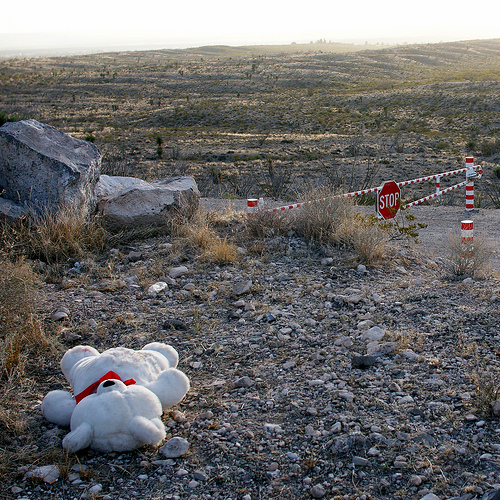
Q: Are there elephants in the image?
A: No, there are no elephants.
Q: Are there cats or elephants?
A: No, there are no elephants or cats.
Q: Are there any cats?
A: No, there are no cats.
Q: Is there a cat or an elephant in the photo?
A: No, there are no cats or elephants.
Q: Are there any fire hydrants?
A: No, there are no fire hydrants.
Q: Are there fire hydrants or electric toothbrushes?
A: No, there are no fire hydrants or electric toothbrushes.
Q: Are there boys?
A: No, there are no boys.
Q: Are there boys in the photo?
A: No, there are no boys.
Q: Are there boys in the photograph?
A: No, there are no boys.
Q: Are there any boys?
A: No, there are no boys.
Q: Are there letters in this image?
A: Yes, there are letters.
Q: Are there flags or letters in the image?
A: Yes, there are letters.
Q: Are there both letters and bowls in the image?
A: No, there are letters but no bowls.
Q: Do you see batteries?
A: No, there are no batteries.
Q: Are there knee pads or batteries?
A: No, there are no batteries or knee pads.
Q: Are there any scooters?
A: No, there are no scooters.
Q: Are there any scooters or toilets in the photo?
A: No, there are no scooters or toilets.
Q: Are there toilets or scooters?
A: No, there are no scooters or toilets.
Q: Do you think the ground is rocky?
A: Yes, the ground is rocky.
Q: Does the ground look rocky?
A: Yes, the ground is rocky.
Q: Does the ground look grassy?
A: No, the ground is rocky.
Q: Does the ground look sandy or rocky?
A: The ground is rocky.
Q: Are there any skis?
A: No, there are no skis.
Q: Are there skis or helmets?
A: No, there are no skis or helmets.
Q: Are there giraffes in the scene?
A: No, there are no giraffes.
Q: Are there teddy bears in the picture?
A: Yes, there is a teddy bear.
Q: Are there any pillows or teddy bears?
A: Yes, there is a teddy bear.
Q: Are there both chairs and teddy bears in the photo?
A: No, there is a teddy bear but no chairs.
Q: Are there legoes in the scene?
A: No, there are no legoes.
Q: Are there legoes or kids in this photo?
A: No, there are no legoes or kids.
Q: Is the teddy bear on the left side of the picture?
A: Yes, the teddy bear is on the left of the image.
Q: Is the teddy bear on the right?
A: No, the teddy bear is on the left of the image.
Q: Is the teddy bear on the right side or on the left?
A: The teddy bear is on the left of the image.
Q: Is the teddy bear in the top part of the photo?
A: No, the teddy bear is in the bottom of the image.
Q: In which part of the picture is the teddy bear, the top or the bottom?
A: The teddy bear is in the bottom of the image.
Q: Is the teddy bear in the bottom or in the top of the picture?
A: The teddy bear is in the bottom of the image.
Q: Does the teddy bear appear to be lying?
A: Yes, the teddy bear is lying.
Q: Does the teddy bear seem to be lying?
A: Yes, the teddy bear is lying.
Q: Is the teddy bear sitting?
A: No, the teddy bear is lying.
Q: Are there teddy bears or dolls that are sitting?
A: No, there is a teddy bear but it is lying.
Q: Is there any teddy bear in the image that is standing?
A: No, there is a teddy bear but it is lying.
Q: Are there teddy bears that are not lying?
A: No, there is a teddy bear but it is lying.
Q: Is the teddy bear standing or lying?
A: The teddy bear is lying.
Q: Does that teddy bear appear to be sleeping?
A: Yes, the teddy bear is sleeping.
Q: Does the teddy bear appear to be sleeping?
A: Yes, the teddy bear is sleeping.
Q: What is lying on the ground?
A: The teddy bear is lying on the ground.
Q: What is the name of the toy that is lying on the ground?
A: The toy is a teddy bear.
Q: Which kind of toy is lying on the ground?
A: The toy is a teddy bear.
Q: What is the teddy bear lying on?
A: The teddy bear is lying on the ground.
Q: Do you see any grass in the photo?
A: Yes, there is grass.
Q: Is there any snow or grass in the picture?
A: Yes, there is grass.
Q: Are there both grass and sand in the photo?
A: No, there is grass but no sand.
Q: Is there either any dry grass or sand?
A: Yes, there is dry grass.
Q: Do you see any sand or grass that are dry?
A: Yes, the grass is dry.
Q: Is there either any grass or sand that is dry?
A: Yes, the grass is dry.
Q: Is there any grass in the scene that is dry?
A: Yes, there is dry grass.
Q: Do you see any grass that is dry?
A: Yes, there is grass that is dry.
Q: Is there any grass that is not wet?
A: Yes, there is dry grass.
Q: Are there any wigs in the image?
A: No, there are no wigs.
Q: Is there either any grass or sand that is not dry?
A: No, there is grass but it is dry.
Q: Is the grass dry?
A: Yes, the grass is dry.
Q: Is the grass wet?
A: No, the grass is dry.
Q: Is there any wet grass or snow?
A: No, there is grass but it is dry.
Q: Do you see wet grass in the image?
A: No, there is grass but it is dry.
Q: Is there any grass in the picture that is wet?
A: No, there is grass but it is dry.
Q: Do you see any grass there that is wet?
A: No, there is grass but it is dry.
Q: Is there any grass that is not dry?
A: No, there is grass but it is dry.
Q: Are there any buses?
A: No, there are no buses.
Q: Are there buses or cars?
A: No, there are no buses or cars.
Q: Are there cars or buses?
A: No, there are no buses or cars.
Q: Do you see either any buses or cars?
A: No, there are no buses or cars.